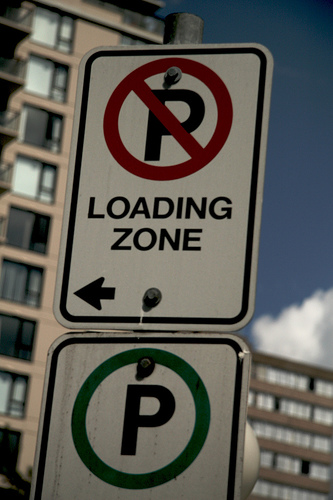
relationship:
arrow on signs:
[72, 277, 116, 311] [44, 31, 277, 340]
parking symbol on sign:
[70, 348, 210, 490] [29, 330, 251, 499]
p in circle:
[120, 384, 175, 456] [71, 348, 211, 490]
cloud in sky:
[250, 286, 332, 369] [155, 1, 331, 352]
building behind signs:
[0, 0, 332, 499] [27, 42, 273, 495]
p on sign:
[120, 384, 175, 456] [29, 330, 251, 499]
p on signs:
[144, 90, 204, 159] [44, 31, 277, 340]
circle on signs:
[104, 58, 233, 182] [44, 31, 277, 340]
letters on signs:
[81, 184, 242, 264] [44, 31, 277, 340]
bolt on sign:
[139, 358, 151, 368] [29, 330, 251, 499]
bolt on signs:
[164, 65, 182, 83] [44, 31, 277, 340]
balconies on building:
[1, 1, 35, 243] [0, 0, 332, 499]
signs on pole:
[44, 31, 277, 340] [162, 12, 204, 43]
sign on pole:
[29, 330, 251, 499] [162, 12, 204, 43]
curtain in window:
[31, 8, 58, 48] [29, 5, 61, 49]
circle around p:
[71, 348, 211, 490] [120, 384, 175, 456]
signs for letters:
[44, 31, 277, 340] [81, 184, 242, 264]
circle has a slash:
[104, 58, 233, 182] [132, 79, 203, 158]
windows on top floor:
[251, 363, 332, 397] [248, 350, 331, 407]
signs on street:
[44, 43, 273, 340] [3, 379, 328, 489]